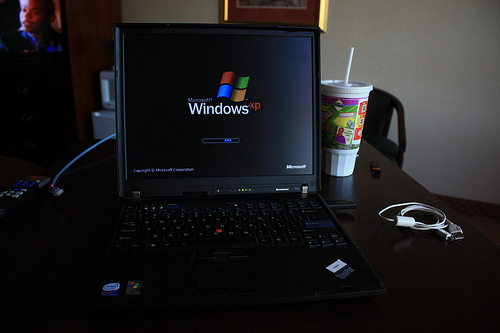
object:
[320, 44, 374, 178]
cup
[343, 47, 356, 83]
straw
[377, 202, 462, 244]
cord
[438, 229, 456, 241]
plugs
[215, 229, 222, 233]
button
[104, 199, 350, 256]
keyboard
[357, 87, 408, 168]
chair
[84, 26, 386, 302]
laptop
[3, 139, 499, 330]
table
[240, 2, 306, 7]
picture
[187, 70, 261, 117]
logo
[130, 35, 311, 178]
screen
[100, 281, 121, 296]
stickers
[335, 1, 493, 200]
wall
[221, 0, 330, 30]
frame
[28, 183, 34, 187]
buttons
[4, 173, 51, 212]
remote control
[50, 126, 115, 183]
wire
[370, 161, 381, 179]
thumbdrive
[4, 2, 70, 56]
television